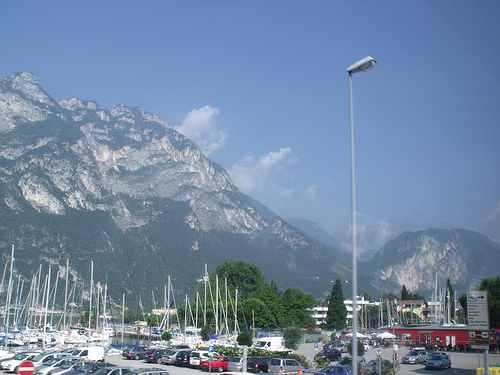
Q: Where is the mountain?
A: Behind the trees.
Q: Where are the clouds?
A: In the sky.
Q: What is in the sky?
A: Clouds.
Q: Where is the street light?
A: On the pole.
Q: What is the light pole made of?
A: Metal.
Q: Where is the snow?
A: On the mountains.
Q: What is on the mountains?
A: Snow.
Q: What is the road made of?
A: Asphalt.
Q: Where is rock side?
A: On mountains.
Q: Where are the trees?
A: In background.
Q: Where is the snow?
A: On mountains.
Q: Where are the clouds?
A: Behind mountain.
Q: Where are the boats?
A: On water.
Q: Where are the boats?
A: In dock.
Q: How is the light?
A: Off.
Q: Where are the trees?
A: Near water.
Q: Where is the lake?
A: Front of mountain.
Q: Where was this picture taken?
A: A marina in the mountains.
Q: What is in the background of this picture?
A: Mountains.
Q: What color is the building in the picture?
A: Red.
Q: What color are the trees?
A: Green.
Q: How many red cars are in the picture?
A: One.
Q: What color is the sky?
A: Blue.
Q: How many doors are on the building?
A: Two.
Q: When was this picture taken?
A: During the day.